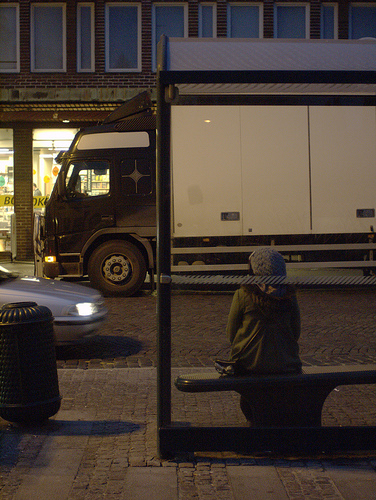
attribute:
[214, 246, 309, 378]
woman — sitting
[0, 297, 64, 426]
trash can — black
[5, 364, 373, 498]
sidewalk — patchwork pattern, stone, grey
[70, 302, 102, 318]
headlight — on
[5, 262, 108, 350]
car — silver, grey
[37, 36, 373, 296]
truck — large, black, white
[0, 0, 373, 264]
building — brick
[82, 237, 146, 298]
tire — black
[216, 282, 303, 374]
coat — green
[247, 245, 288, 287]
hat — grey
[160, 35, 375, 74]
canopy top — glass, white